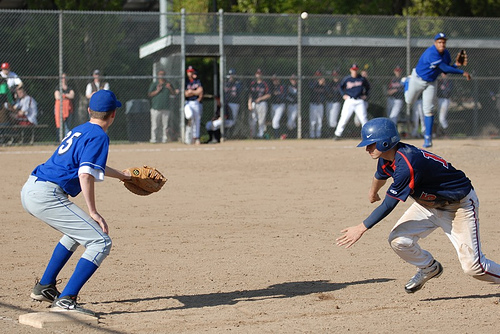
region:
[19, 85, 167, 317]
Man wearing a blue uniform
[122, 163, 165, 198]
Light brown leather catcher's mitt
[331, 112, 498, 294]
Baseball player running to a base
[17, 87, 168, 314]
Man standing next to a base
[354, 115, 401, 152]
Blue Nike helmet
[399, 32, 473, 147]
Man throwing a baseball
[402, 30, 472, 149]
Man in a blue shirt and gray pants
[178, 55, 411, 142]
Baseball players standing near the bench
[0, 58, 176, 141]
People watching a baseball game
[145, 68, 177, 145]
Man in a green shirt and khaki pants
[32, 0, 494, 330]
these fellas are playing baseball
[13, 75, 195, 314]
this fella has a blue shirt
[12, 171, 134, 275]
he is wearing grey pants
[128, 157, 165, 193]
his glove is brown leather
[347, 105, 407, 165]
the player's helmet is blue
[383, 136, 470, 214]
he is wearing a dark blue jersey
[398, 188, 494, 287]
he is wearing white pants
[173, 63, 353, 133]
the rest of the team in the dugout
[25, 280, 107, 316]
this player is wearing dark spikes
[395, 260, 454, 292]
this player is wearing white spikes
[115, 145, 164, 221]
kid wearing a catchers mit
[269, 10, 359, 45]
baseball flying through the air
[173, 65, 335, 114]
people standing in the dug out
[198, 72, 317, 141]
people standing near the dug out's fence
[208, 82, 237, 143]
a person sitting in the dug out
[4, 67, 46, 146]
people watching a baseball game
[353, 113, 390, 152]
a kid wearing a blue helmet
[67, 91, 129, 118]
a kid wearing a blue cap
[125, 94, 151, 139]
a trashcan standing outside a baseball field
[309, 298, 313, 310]
part of a shadow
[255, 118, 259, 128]
part of a fence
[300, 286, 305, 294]
part of a shadow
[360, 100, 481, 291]
a kid running to base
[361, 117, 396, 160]
a kid wearing a blue helmet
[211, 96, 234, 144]
a kid sitting in a dug out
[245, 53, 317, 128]
kids standing in a dug out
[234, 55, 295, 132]
kids standing near a fence in a dugout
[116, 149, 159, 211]
a kid holding a catchers mitt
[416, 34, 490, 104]
a guy throwing a baseball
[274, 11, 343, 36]
baseball flying through the air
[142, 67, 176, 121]
a guy holding onto a fence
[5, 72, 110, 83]
people watching a baseball game